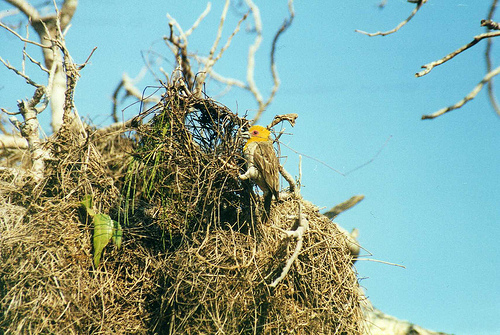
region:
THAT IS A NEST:
[15, 94, 355, 326]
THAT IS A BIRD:
[239, 107, 276, 192]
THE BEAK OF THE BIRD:
[239, 129, 247, 145]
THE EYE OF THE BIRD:
[251, 131, 262, 137]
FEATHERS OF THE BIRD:
[264, 144, 269, 176]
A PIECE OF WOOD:
[246, 0, 273, 72]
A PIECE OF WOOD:
[275, 5, 297, 47]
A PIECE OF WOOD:
[354, 17, 409, 53]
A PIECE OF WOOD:
[416, 49, 464, 86]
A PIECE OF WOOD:
[427, 97, 469, 129]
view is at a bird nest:
[145, 63, 308, 300]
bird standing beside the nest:
[216, 111, 292, 204]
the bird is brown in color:
[238, 125, 291, 187]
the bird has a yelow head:
[244, 122, 277, 155]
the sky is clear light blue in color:
[419, 173, 481, 224]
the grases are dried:
[213, 248, 332, 310]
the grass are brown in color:
[204, 245, 301, 297]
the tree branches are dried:
[163, 20, 251, 77]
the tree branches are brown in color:
[187, 26, 261, 88]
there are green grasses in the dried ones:
[123, 128, 177, 187]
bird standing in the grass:
[225, 121, 293, 207]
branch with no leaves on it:
[412, 70, 499, 134]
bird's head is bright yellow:
[242, 122, 276, 145]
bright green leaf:
[85, 203, 122, 263]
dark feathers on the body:
[257, 141, 289, 199]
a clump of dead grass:
[10, 124, 357, 334]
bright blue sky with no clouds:
[0, 2, 497, 332]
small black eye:
[251, 128, 261, 138]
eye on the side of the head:
[253, 129, 260, 138]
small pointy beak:
[239, 131, 251, 139]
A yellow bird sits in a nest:
[224, 119, 289, 206]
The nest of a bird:
[15, 91, 367, 334]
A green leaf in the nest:
[71, 201, 127, 266]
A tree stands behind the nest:
[180, 1, 298, 130]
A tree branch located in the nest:
[269, 154, 311, 291]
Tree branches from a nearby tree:
[355, 1, 498, 136]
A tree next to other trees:
[0, 1, 104, 143]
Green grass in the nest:
[107, 101, 179, 233]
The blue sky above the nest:
[3, 2, 493, 324]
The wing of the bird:
[253, 143, 282, 200]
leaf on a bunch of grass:
[62, 183, 136, 257]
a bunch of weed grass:
[19, 84, 371, 331]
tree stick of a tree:
[385, 10, 498, 128]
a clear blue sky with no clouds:
[389, 133, 494, 224]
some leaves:
[79, 178, 124, 264]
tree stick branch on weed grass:
[257, 188, 319, 283]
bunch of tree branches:
[3, 19, 118, 184]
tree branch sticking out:
[115, 3, 310, 126]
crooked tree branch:
[407, 5, 497, 127]